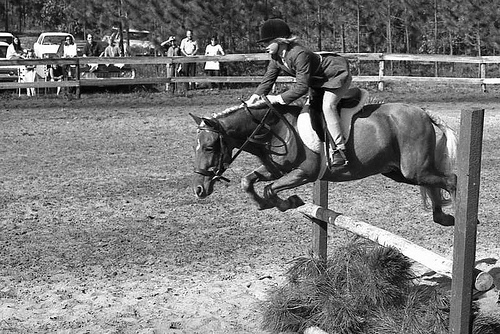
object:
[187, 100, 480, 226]
horse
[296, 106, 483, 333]
fence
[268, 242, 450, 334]
patch of grass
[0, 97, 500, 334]
dirt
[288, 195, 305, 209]
hoof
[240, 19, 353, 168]
rider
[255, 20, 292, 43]
helmet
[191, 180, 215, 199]
nose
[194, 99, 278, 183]
reign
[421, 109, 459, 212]
tail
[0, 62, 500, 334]
field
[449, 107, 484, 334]
post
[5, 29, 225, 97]
people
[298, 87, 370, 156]
saddle blanket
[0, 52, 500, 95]
fence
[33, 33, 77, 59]
car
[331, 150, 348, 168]
boot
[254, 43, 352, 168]
riding outfit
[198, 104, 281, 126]
mane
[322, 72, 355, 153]
pants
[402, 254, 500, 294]
shadow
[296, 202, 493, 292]
rail